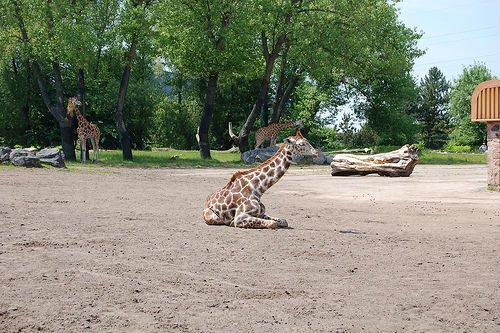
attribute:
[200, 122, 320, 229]
giraffe — SITTING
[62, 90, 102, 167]
giraffe — SITTING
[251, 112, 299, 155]
giraffe — STANDING